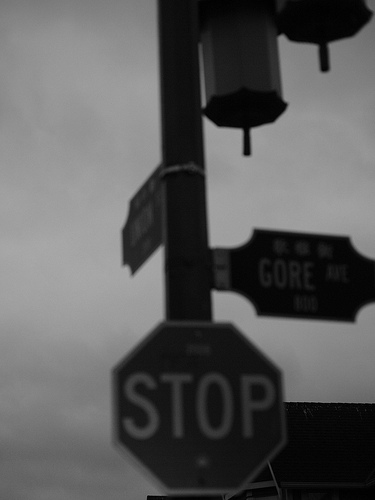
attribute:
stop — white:
[127, 371, 274, 447]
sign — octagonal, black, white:
[105, 318, 293, 496]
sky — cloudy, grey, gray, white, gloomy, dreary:
[2, 3, 374, 499]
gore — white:
[256, 253, 316, 296]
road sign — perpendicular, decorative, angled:
[117, 171, 167, 270]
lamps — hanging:
[192, 2, 371, 156]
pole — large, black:
[157, 3, 213, 323]